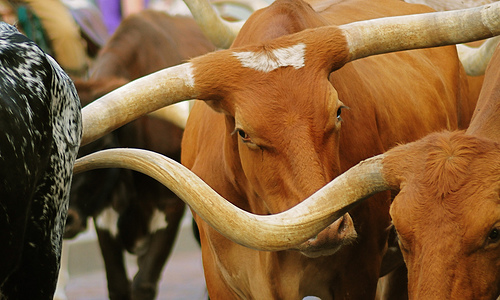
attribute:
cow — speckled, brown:
[71, 1, 499, 283]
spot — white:
[234, 47, 311, 71]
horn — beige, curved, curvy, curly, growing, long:
[70, 147, 397, 246]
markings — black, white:
[1, 23, 82, 300]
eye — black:
[231, 124, 253, 139]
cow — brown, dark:
[57, 12, 207, 288]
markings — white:
[94, 203, 169, 234]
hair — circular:
[407, 135, 481, 197]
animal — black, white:
[1, 21, 85, 299]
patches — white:
[94, 202, 169, 237]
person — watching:
[1, 2, 173, 84]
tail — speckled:
[40, 51, 85, 249]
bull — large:
[180, 1, 473, 300]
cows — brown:
[54, 2, 499, 293]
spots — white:
[1, 19, 84, 299]